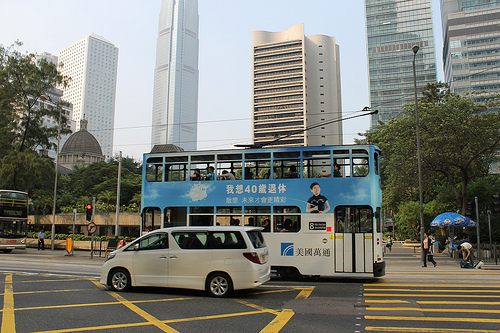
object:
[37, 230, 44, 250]
man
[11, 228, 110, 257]
sidewalk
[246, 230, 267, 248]
window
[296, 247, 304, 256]
chinese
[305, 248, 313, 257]
chinese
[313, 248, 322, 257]
chinese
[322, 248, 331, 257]
chinese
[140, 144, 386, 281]
double-decker bus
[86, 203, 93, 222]
light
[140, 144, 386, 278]
bus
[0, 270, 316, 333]
stripes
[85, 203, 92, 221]
stop light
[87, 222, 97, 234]
sign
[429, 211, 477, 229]
umberella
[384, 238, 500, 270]
sidewalk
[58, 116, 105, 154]
roof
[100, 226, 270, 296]
cars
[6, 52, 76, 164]
building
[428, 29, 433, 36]
windows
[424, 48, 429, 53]
windows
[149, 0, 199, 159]
skycraper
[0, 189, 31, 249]
bus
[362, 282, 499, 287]
stripe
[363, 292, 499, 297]
stripe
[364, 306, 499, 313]
stripe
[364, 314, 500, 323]
stripe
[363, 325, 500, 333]
stripe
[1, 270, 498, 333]
street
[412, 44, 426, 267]
lightpole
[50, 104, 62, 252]
lightpole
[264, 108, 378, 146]
lightpole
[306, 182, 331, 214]
man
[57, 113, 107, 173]
building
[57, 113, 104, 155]
dome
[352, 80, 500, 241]
tree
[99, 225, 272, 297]
van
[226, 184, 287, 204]
chinese writing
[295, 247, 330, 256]
chinese writing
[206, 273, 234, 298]
wheel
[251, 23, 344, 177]
building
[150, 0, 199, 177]
building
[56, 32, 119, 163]
building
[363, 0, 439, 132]
building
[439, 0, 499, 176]
building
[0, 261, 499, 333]
road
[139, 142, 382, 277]
side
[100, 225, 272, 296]
car